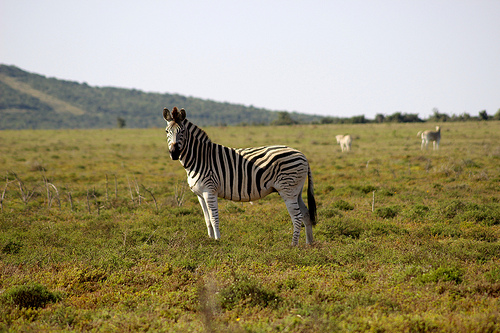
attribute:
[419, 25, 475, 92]
clouds — white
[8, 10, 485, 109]
sky — blue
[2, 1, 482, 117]
sky — overcast, blue, cloudless, clear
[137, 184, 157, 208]
branch — dry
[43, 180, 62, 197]
branch — dry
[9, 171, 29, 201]
branch — dry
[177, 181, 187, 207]
branch — dry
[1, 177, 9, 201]
branch — dry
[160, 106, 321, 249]
zebra — white, black, large, striped, looking, staring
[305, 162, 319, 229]
tail — black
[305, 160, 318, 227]
tail — long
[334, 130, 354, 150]
animal — white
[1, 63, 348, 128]
hill — green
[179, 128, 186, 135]
eye — black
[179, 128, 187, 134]
eye — small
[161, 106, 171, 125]
ear — dark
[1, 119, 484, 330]
field — grassy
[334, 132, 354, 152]
llama — white